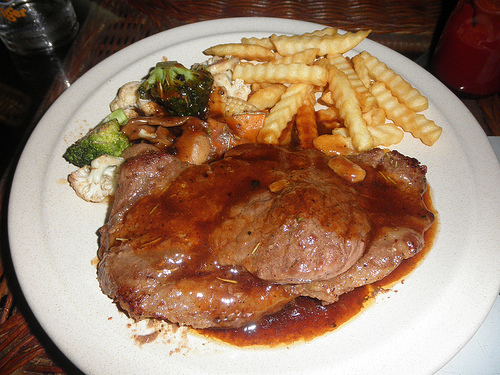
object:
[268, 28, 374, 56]
fries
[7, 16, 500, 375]
plate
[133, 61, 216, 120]
broccoli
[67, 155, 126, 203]
cauliflower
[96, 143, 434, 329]
meat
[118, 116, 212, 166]
mushroom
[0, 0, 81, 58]
glass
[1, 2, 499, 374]
table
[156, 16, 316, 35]
edge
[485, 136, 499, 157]
napkin